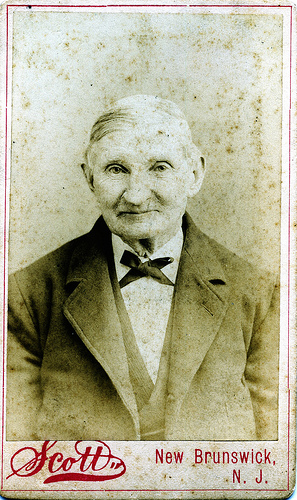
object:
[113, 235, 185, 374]
shirt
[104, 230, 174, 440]
vest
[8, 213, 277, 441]
coat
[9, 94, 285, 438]
man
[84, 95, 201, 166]
grey hair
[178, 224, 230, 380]
lapel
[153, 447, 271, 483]
kitten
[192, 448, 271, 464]
letter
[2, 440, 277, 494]
sign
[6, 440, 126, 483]
words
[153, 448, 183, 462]
words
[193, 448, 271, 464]
words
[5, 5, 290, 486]
border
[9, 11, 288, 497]
photo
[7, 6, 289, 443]
sign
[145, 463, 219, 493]
rust spots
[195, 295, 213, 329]
button hole